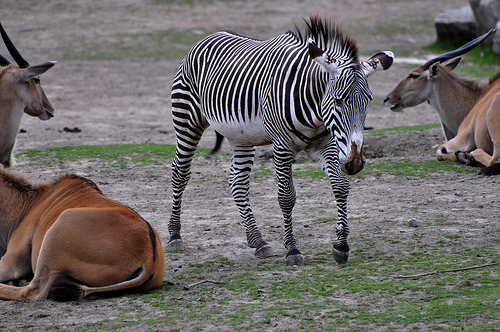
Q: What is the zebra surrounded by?
A: Gazelles.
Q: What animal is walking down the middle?
A: Zebra.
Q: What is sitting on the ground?
A: Giselles.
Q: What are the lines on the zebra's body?
A: Stripes.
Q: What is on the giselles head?
A: Horns.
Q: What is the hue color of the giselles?
A: Brown.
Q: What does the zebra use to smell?
A: Nose.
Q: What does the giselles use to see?
A: Eyes.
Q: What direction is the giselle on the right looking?
A: Left.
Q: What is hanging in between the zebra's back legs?
A: A tail.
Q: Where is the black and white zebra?
A: Walking between other animals.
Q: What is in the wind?
A: All four animals.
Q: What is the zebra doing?
A: Walking.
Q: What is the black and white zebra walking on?
A: Rocks and grass.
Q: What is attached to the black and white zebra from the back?
A: Short black tail.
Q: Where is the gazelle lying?
A: On ground.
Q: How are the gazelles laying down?
A: On their sides.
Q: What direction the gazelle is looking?
A: To the right.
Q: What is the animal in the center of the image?
A: Zebra.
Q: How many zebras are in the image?
A: One.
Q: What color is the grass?
A: Green.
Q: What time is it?
A: Daytime.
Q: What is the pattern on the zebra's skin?
A: Stripes.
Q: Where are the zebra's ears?
A: On its head.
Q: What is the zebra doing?
A: Standing.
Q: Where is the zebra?
A: Near a herd of animal.